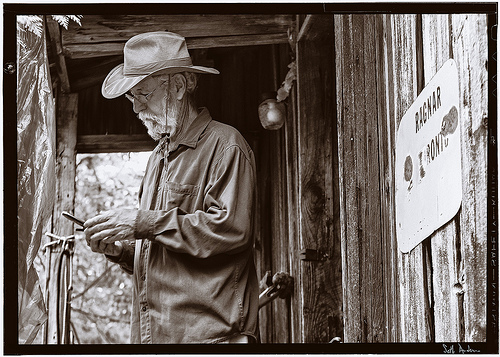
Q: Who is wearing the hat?
A: Old man.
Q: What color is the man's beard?
A: White.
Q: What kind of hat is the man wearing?
A: Cowboy.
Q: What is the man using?
A: Cellphone.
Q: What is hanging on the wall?
A: A sign.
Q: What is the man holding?
A: A Cell Phone.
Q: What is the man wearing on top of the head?
A: A hat.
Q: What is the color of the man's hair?
A: White.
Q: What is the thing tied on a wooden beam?
A: A rope.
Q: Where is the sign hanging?
A: On the wall.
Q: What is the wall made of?
A: Wood.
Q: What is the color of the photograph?
A: Black and white.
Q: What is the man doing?
A: Holding a phone.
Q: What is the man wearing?
A: A hat.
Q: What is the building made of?
A: Wood.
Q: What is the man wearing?
A: A shirt.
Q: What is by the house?
A: A tree.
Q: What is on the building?
A: A sign.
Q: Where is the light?
A: On the building.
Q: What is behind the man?
A: The doorway.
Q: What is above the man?
A: The roof.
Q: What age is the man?
A: Old.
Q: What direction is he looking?
A: Down.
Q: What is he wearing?
A: A hat.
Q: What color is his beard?
A: Gray.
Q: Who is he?
A: An old man.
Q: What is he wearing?
A: A button up shirt.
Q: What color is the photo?
A: Black and white.